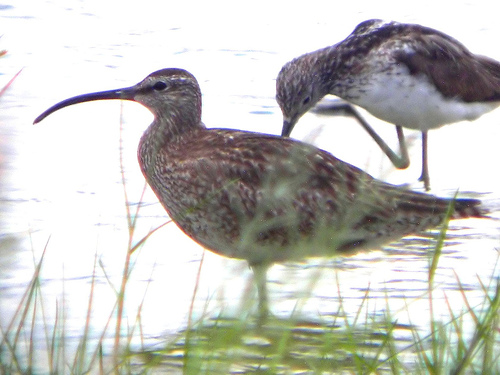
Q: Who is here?
A: Birds.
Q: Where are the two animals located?
A: The water.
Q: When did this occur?
A: During the day.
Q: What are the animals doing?
A: Standing in the water.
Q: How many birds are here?
A: Two.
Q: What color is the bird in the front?
A: Brown and white.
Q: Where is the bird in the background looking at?
A: Down.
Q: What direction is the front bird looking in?
A: West.